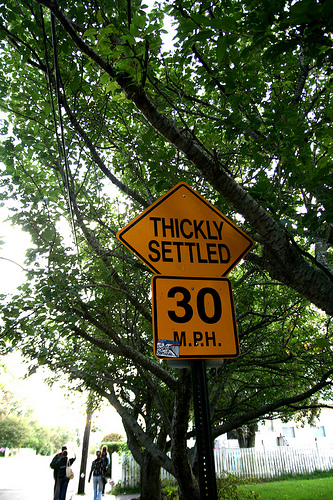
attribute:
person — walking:
[87, 451, 110, 499]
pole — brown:
[78, 389, 93, 496]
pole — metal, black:
[189, 357, 219, 498]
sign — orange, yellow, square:
[148, 274, 241, 363]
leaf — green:
[159, 49, 174, 59]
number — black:
[167, 286, 220, 322]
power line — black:
[41, 2, 78, 256]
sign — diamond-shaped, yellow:
[119, 182, 255, 275]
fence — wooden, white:
[110, 449, 331, 492]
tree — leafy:
[0, 212, 331, 497]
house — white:
[213, 389, 331, 441]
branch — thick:
[43, 2, 330, 316]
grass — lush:
[165, 474, 331, 499]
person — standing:
[48, 447, 75, 499]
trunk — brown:
[139, 453, 164, 498]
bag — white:
[66, 459, 76, 482]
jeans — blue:
[92, 475, 107, 498]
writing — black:
[147, 218, 232, 266]